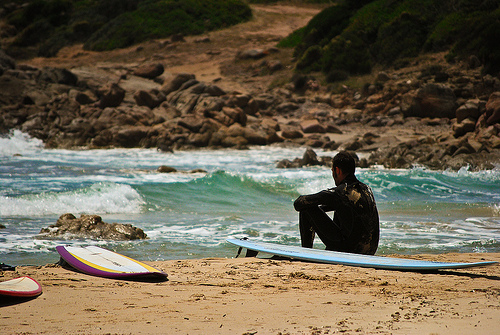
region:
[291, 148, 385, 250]
person sitting on beach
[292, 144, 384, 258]
wet person sitting at edge of beach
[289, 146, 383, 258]
person in black wetsuit sitting on beach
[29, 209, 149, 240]
large rock in the water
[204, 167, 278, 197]
wave ripple in the water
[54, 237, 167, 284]
purple yellow and white boogie board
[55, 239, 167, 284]
purple yellow and white boogie board lying at the edge of water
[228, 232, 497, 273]
blue surfboard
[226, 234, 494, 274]
blue surfboard laying on the beach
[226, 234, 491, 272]
blue surfboard next to man in black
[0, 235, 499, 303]
Three objects used for surfing.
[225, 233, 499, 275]
A long light blue surfboard.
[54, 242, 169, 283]
A purple, yellow, and white surfboard.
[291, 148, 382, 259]
A man sitting on the beach.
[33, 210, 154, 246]
Rocks in the ocean.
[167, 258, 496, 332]
Indentions in the sand on the beach.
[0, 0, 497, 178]
A rocky hill by the beach.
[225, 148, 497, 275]
A man sitting next to a surfboard.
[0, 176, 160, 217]
A wave in the ocean.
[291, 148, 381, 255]
A man looking out over the ocean.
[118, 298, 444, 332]
The beach on the sand is wet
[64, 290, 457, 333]
The sand on the beach is the color brown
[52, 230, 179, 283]
The surfboard is white, yellow, and purple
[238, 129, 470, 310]
The surfer sitting on the beach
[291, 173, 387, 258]
The surfer has on a wet suit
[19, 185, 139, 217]
The white water in the ocean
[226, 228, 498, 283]
The surfboard is the color blue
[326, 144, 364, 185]
The head of the surfer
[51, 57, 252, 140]
The rocks to the mountain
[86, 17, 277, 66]
The dirt on the ground is dry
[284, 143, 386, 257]
man sitting on the sand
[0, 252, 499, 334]
brown sand near the shore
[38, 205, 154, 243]
rock jutting from the water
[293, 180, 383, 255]
man's black colored wetsuit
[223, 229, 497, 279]
blue surfboard on the sand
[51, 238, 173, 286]
white, yellow, and purple surfboard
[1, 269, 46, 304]
white and pink surfboard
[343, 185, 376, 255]
sand spots on a black wetsuit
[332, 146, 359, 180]
man's dark hair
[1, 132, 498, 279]
water at a beach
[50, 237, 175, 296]
purple surfboard on beach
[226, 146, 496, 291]
man sitting beside surf board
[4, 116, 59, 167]
ocean spray on rocky shore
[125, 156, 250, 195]
ocean waves and rocks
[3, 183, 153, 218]
ocean wave curling onto shore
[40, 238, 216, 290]
shoreline and a surfboard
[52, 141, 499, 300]
man and two surfboards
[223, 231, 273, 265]
fin of a surfboard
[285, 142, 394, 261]
back of man facing ocean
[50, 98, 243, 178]
water and rocky shoreline